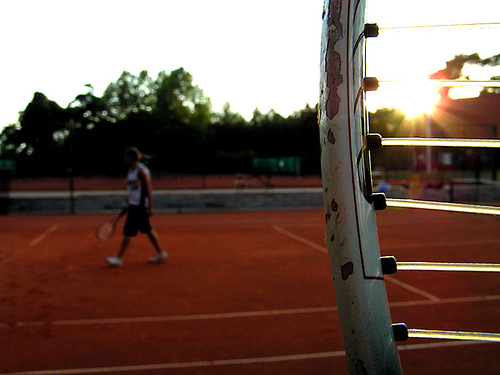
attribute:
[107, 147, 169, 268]
man — walking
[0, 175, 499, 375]
tennis court — red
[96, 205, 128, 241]
tennis racket — black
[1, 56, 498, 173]
trees — green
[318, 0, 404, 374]
pole — rusty, metal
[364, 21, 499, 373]
cables — plastic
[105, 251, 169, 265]
sneakers — white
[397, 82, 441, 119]
sun — shinning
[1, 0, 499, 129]
sky — clear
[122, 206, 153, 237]
shorts — black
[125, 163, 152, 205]
shirt — white